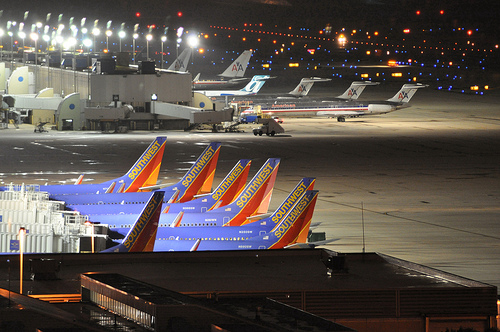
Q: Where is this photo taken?
A: Airport.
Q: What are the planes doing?
A: Boarding passengers.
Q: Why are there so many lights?
A: To light the runway for the pilots.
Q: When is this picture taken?
A: Night time.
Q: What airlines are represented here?
A: Southwest and American Airlines.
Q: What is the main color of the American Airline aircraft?
A: Black.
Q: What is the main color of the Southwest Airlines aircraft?
A: Blue.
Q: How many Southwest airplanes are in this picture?
A: Seven.